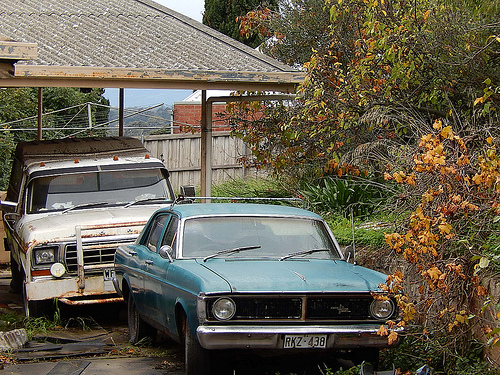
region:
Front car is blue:
[113, 203, 398, 363]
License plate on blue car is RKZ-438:
[281, 330, 342, 358]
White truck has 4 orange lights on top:
[18, 144, 167, 181]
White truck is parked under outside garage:
[11, 141, 173, 302]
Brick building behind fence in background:
[164, 85, 304, 139]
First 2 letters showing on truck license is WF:
[98, 263, 128, 287]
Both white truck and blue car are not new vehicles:
[0, 135, 411, 368]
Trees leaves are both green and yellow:
[305, 30, 499, 329]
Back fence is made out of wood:
[148, 120, 294, 191]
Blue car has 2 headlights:
[202, 283, 408, 336]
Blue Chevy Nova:
[113, 201, 414, 368]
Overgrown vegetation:
[298, 76, 495, 279]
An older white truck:
[8, 136, 181, 321]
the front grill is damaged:
[197, 275, 396, 345]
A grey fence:
[143, 116, 303, 190]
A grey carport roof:
[14, 21, 346, 143]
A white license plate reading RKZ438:
[275, 326, 350, 356]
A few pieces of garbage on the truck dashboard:
[17, 185, 185, 214]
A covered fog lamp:
[29, 253, 96, 309]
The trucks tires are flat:
[4, 262, 70, 357]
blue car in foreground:
[125, 205, 409, 373]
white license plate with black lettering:
[267, 324, 355, 372]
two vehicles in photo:
[15, 102, 346, 373]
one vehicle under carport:
[8, 11, 226, 329]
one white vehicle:
[17, 127, 185, 348]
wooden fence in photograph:
[132, 114, 397, 221]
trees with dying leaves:
[162, 17, 497, 354]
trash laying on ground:
[4, 304, 111, 374]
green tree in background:
[15, 84, 132, 221]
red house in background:
[50, 74, 235, 156]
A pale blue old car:
[111, 185, 402, 372]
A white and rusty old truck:
[6, 132, 178, 326]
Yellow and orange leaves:
[367, 137, 498, 349]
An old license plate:
[272, 312, 336, 359]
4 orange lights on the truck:
[24, 142, 165, 177]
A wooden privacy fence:
[159, 132, 309, 203]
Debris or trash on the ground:
[13, 301, 117, 373]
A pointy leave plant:
[284, 161, 399, 226]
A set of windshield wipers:
[195, 216, 326, 283]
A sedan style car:
[102, 186, 488, 362]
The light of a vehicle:
[216, 292, 234, 322]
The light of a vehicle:
[366, 290, 395, 319]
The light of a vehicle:
[30, 248, 56, 262]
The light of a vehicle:
[28, 268, 56, 281]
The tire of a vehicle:
[178, 310, 209, 370]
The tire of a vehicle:
[121, 288, 154, 350]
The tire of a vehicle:
[20, 262, 45, 317]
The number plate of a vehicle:
[282, 332, 326, 348]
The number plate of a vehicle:
[104, 265, 123, 285]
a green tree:
[299, 167, 369, 224]